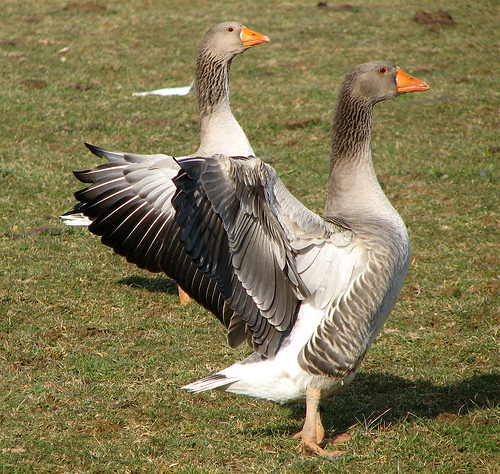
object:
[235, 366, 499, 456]
shadow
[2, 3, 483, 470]
ground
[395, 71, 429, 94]
beak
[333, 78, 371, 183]
neck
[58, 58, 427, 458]
bird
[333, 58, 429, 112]
head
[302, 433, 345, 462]
claw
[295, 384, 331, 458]
leg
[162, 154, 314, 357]
wing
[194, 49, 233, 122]
neck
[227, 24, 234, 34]
eye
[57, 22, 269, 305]
bird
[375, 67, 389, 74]
eye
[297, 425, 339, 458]
foot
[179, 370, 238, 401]
tail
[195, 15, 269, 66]
head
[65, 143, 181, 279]
feathers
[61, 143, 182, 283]
wing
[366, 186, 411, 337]
breast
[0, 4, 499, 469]
lawn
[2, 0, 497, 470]
grass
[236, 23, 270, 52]
beak